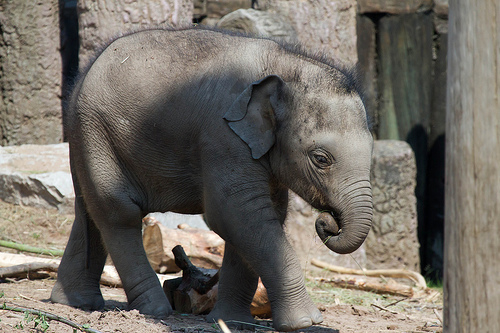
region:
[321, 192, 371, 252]
The trunk of the elephant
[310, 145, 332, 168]
The right eye of the elephant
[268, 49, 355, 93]
Hair on the elephant's head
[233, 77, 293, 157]
The right ear of the elephant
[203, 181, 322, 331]
The front legs of the elephant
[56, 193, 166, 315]
The elephant's back legs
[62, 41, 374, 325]
A small elephant in an enclosure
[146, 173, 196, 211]
The stomach of the elephant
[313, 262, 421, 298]
Sticks near the elephant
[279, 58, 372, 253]
The head of the elephant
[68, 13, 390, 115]
black hair on the baby elephant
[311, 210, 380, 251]
baby elephant's trunk is rolled up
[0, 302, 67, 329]
leaves on the branch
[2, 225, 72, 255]
green tree branch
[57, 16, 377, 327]
baby elephant is grey color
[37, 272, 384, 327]
baby elephant is walking in the dirt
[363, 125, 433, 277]
stone wall next to tree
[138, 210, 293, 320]
wood logs on the side of the baby elephant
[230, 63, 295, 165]
baby elephant's ear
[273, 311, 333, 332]
toes on the baby elephant's foot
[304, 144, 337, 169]
the right eye of the elephant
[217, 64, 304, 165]
the right ear of the elephant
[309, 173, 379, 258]
the trunk of the elephant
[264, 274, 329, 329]
the front right foot of the elephant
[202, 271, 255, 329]
the front left foot of the elephant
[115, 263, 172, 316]
the back right foot of the elephant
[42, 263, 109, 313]
the back left foot of the elephant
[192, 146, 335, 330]
the front right leg of the elephant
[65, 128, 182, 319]
the back right leg of the elephant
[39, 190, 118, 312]
the back left leg of the elephant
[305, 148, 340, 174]
baby elephant right eye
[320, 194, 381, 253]
baby elephants trunk curled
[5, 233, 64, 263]
green branch on the ground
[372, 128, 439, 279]
brick cement piece behind elephant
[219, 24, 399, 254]
head of the baby elephant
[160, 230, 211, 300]
piece of wood on the ground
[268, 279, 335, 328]
elephants right hoof on the ground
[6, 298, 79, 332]
tree branch on the ground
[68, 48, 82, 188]
fine hair on elephant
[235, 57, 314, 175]
elephants right flappy ear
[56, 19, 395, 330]
Small baby elephant at zoo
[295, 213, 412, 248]
Curled trunk of baby elephant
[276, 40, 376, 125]
Small fur growing on elephant's head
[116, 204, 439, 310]
Cut up tree branches on ground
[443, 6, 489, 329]
Tall wooden pole on right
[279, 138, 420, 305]
Stone block in background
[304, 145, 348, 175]
Tired eye of small elephant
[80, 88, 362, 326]
Shadow of pole cast on elephant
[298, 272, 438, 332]
Short grass growing in pen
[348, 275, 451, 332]
Small sticks laying on ground